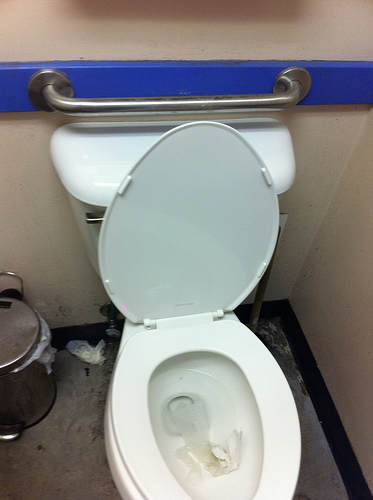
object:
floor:
[22, 427, 104, 497]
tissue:
[161, 394, 240, 477]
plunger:
[250, 285, 268, 328]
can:
[0, 268, 58, 442]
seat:
[119, 320, 299, 500]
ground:
[242, 54, 256, 63]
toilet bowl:
[45, 107, 302, 499]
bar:
[25, 66, 314, 119]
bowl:
[144, 347, 266, 500]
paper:
[63, 338, 108, 368]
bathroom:
[2, 0, 373, 500]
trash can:
[1, 268, 60, 444]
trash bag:
[33, 313, 55, 373]